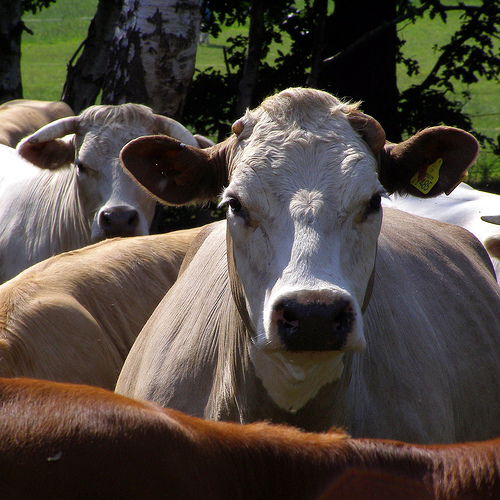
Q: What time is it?
A: Afternoon.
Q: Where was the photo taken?
A: Outside somewhere.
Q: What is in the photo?
A: Cows.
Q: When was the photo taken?
A: During the daytime.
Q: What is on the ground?
A: Grass.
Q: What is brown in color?
A: Fur.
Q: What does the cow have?
A: Ears.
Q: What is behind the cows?
A: Trees.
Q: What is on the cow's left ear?
A: An identification mark.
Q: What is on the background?
A: A green open field.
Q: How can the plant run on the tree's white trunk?
A: Because it is a climbing wild plant.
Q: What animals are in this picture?
A: Cows.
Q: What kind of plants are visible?
A: Trees and grass.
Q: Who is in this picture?
A: Cows.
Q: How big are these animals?
A: Large.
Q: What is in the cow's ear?
A: Yellow tag.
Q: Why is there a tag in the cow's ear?
A: Identification.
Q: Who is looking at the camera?
A: Two cows.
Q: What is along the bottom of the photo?
A: Brown cow.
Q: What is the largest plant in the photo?
A: Tree.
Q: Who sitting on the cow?
A: No one.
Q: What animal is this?
A: Cow.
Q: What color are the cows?
A: Brown.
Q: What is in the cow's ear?
A: Tag.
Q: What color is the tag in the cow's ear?
A: Yellow.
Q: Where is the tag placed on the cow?
A: Ear.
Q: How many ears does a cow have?
A: Two.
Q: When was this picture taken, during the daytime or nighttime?
A: Daytime.